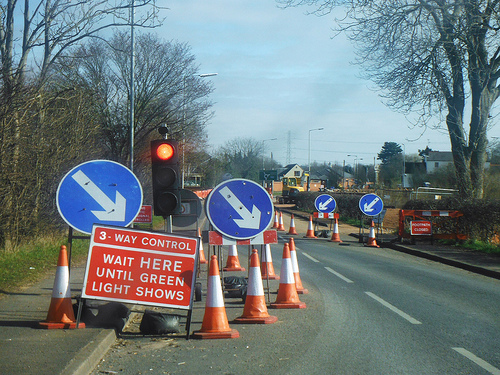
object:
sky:
[4, 5, 497, 164]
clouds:
[307, 92, 422, 150]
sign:
[206, 178, 274, 240]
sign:
[55, 159, 142, 235]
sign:
[359, 190, 388, 218]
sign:
[81, 226, 197, 311]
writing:
[91, 232, 191, 302]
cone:
[192, 255, 240, 339]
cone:
[38, 246, 84, 331]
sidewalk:
[2, 252, 95, 373]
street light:
[150, 136, 184, 215]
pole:
[150, 121, 182, 232]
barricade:
[399, 208, 469, 245]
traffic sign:
[259, 168, 277, 180]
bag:
[139, 309, 181, 335]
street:
[114, 198, 498, 374]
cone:
[233, 249, 279, 325]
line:
[297, 238, 433, 340]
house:
[262, 163, 321, 192]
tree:
[376, 142, 403, 190]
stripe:
[205, 275, 225, 308]